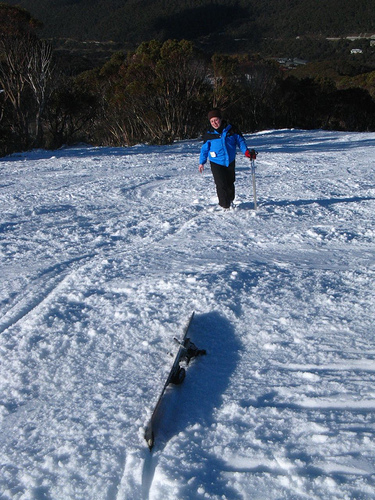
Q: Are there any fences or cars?
A: No, there are no cars or fences.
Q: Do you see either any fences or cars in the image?
A: No, there are no cars or fences.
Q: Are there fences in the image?
A: No, there are no fences.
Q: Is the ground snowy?
A: Yes, the ground is snowy.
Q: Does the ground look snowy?
A: Yes, the ground is snowy.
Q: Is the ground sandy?
A: No, the ground is snowy.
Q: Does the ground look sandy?
A: No, the ground is snowy.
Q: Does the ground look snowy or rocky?
A: The ground is snowy.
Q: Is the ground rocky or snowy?
A: The ground is snowy.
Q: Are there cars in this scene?
A: No, there are no cars.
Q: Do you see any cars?
A: No, there are no cars.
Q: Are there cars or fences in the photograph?
A: No, there are no cars or fences.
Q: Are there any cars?
A: No, there are no cars.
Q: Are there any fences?
A: No, there are no fences.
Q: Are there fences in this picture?
A: No, there are no fences.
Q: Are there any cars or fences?
A: No, there are no fences or cars.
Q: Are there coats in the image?
A: Yes, there is a coat.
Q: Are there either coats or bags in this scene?
A: Yes, there is a coat.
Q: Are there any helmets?
A: No, there are no helmets.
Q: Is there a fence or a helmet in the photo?
A: No, there are no helmets or fences.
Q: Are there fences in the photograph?
A: No, there are no fences.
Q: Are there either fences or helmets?
A: No, there are no fences or helmets.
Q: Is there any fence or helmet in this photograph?
A: No, there are no fences or helmets.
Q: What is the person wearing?
A: The person is wearing a glove.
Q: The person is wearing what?
A: The person is wearing a glove.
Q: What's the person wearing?
A: The person is wearing a glove.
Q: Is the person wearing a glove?
A: Yes, the person is wearing a glove.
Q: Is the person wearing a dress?
A: No, the person is wearing a glove.